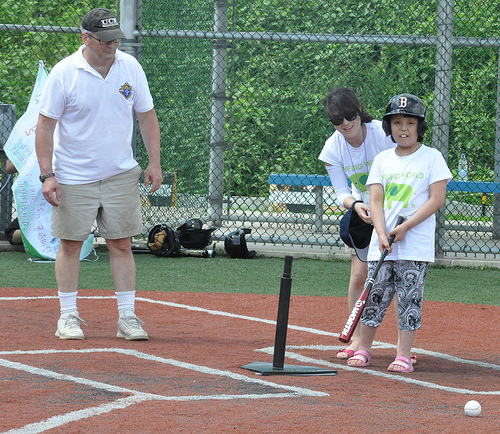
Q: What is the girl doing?
A: Batting.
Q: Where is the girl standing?
A: At the tee.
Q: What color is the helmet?
A: Black.